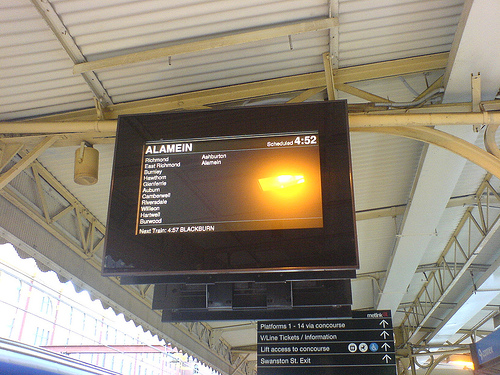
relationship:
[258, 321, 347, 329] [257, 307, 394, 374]
letters on directional sign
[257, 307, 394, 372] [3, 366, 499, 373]
directional sign on platform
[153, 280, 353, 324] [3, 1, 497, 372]
sign hanging from ceiling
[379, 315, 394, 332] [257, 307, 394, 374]
arrows on directional sign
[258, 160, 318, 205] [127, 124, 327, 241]
light shining on screen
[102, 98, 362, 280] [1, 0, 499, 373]
travel marquee at building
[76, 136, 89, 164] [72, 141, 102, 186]
metal mount on white-tubular light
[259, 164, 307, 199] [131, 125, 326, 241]
light off monitor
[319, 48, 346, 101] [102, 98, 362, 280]
white-metal mounts supporting travel marquee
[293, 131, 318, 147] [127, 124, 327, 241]
digital-time displayed on screen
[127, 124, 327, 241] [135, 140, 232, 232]
screen showing train schedule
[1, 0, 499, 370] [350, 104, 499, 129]
building has pipe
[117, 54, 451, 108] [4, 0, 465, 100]
beam on roof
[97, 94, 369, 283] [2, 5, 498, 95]
board on ceiling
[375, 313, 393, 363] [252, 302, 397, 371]
arrows on sign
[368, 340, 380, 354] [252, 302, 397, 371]
circle on sign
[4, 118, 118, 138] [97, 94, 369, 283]
pipe behind board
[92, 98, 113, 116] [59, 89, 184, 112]
bracket holds pipe